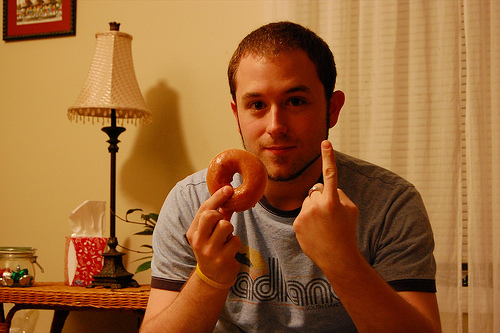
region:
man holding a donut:
[157, 24, 417, 318]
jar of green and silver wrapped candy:
[0, 242, 48, 297]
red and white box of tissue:
[56, 193, 111, 289]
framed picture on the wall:
[2, 3, 87, 50]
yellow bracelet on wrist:
[180, 261, 248, 298]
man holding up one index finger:
[226, 15, 392, 313]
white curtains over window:
[383, 5, 496, 170]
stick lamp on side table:
[16, 10, 162, 315]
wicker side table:
[5, 276, 136, 326]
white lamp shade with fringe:
[50, 17, 157, 142]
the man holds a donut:
[155, 15, 447, 328]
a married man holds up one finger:
[281, 140, 368, 246]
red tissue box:
[35, 185, 150, 289]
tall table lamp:
[59, 7, 159, 291]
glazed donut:
[201, 145, 268, 217]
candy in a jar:
[0, 237, 45, 296]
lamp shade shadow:
[113, 56, 200, 221]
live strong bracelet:
[183, 259, 248, 295]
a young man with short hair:
[203, 22, 358, 209]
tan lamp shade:
[68, 16, 149, 125]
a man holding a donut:
[154, 37, 380, 306]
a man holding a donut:
[167, 8, 340, 187]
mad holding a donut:
[139, 18, 446, 330]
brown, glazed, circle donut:
[202, 146, 269, 212]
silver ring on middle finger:
[304, 181, 326, 196]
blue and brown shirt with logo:
[142, 162, 444, 332]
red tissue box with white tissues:
[61, 196, 113, 286]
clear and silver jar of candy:
[2, 241, 46, 285]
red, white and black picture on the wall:
[2, 1, 80, 43]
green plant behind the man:
[112, 204, 160, 278]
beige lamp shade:
[62, 29, 156, 130]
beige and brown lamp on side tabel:
[64, 19, 154, 291]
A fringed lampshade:
[61, 16, 161, 132]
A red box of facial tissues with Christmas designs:
[58, 196, 111, 288]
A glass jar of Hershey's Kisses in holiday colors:
[0, 242, 48, 289]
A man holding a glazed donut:
[133, 8, 445, 329]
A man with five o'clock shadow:
[221, 12, 354, 187]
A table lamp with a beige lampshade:
[61, 16, 156, 293]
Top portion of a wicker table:
[0, 285, 145, 331]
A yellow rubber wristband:
[183, 263, 246, 294]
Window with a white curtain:
[346, 3, 490, 331]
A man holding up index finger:
[134, 20, 446, 330]